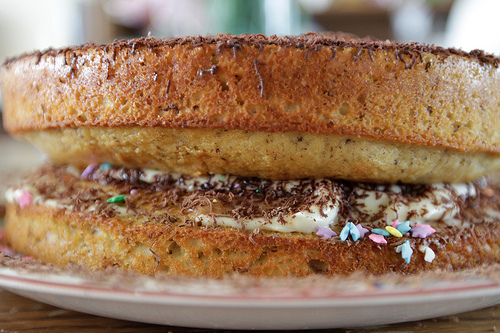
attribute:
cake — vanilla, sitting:
[2, 32, 499, 298]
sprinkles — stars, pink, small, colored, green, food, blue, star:
[108, 194, 125, 202]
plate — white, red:
[1, 268, 498, 330]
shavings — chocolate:
[36, 171, 499, 228]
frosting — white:
[31, 167, 499, 239]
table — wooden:
[2, 289, 499, 332]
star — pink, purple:
[370, 234, 388, 246]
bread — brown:
[4, 36, 497, 183]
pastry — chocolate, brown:
[2, 35, 497, 291]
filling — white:
[29, 160, 499, 232]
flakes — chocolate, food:
[399, 219, 410, 233]